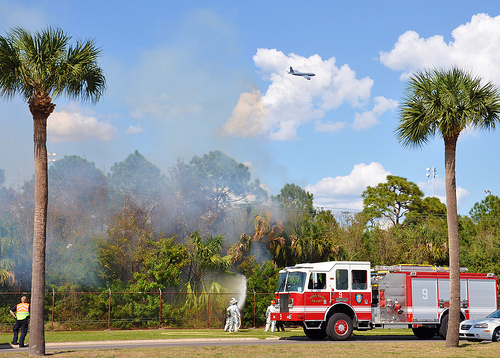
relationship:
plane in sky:
[287, 63, 317, 84] [1, 0, 499, 229]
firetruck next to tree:
[268, 261, 500, 340] [392, 67, 500, 347]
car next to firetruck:
[460, 306, 500, 342] [268, 261, 500, 340]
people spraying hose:
[224, 297, 286, 335] [235, 274, 251, 335]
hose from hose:
[229, 269, 250, 314] [235, 274, 251, 335]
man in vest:
[6, 295, 31, 349] [14, 302, 29, 321]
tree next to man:
[0, 26, 106, 358] [6, 295, 31, 349]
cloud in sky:
[47, 12, 500, 230] [1, 0, 499, 229]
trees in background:
[1, 146, 499, 328] [4, 146, 494, 325]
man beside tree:
[6, 295, 31, 349] [0, 26, 106, 358]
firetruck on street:
[268, 261, 500, 340] [0, 336, 494, 357]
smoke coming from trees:
[2, 4, 306, 288] [1, 146, 499, 328]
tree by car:
[392, 67, 500, 347] [460, 306, 500, 342]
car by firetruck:
[460, 306, 500, 342] [268, 261, 500, 340]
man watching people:
[6, 295, 31, 349] [224, 297, 286, 335]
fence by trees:
[0, 288, 276, 330] [1, 146, 499, 328]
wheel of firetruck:
[326, 310, 355, 342] [268, 261, 500, 340]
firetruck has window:
[268, 261, 500, 340] [275, 271, 307, 293]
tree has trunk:
[392, 67, 500, 347] [445, 137, 462, 347]